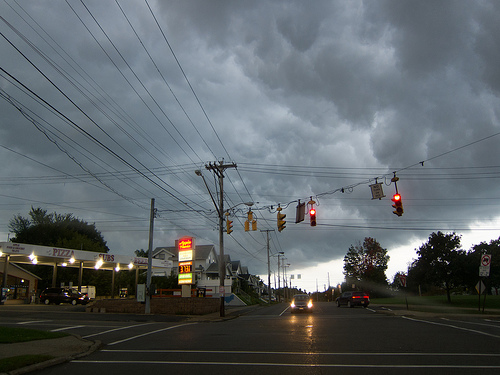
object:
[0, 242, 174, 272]
canopy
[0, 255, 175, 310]
gas station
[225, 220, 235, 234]
light case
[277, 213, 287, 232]
light case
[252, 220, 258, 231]
light case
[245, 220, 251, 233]
light case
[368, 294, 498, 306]
grass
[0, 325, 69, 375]
grass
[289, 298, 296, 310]
light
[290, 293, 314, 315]
car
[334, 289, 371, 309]
car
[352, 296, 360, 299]
light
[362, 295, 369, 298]
light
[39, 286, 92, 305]
car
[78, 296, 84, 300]
light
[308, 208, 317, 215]
light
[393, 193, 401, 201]
light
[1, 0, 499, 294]
sky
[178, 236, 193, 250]
sig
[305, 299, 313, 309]
headlignt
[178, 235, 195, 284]
sign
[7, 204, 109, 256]
tree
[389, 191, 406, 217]
signal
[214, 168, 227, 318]
pole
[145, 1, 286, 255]
wires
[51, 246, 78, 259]
sign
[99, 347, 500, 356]
lines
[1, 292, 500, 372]
road